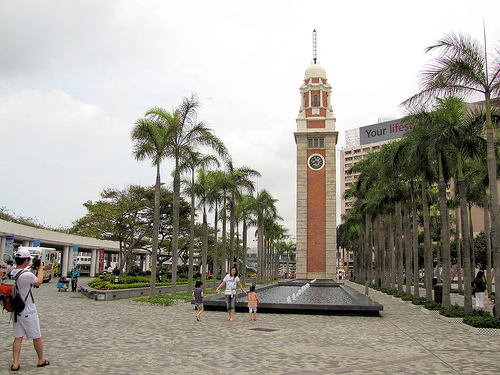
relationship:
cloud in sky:
[5, 86, 132, 190] [2, 2, 499, 225]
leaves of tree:
[421, 32, 485, 66] [404, 24, 499, 327]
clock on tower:
[305, 149, 326, 173] [292, 26, 341, 280]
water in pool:
[224, 282, 355, 304] [191, 277, 384, 313]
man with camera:
[2, 249, 51, 371] [30, 254, 45, 269]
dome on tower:
[303, 61, 328, 83] [292, 26, 341, 280]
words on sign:
[365, 125, 404, 138] [358, 113, 416, 146]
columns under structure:
[59, 247, 76, 281] [2, 217, 207, 256]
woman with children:
[212, 266, 245, 322] [189, 279, 260, 323]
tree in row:
[404, 24, 499, 327] [342, 23, 499, 330]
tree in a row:
[404, 24, 499, 327] [342, 23, 499, 330]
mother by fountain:
[212, 266, 245, 322] [191, 277, 384, 313]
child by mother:
[190, 276, 207, 324] [212, 266, 245, 322]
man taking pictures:
[2, 249, 51, 371] [30, 254, 45, 269]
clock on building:
[305, 149, 326, 173] [292, 26, 341, 280]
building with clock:
[292, 26, 341, 280] [305, 149, 326, 173]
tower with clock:
[292, 26, 341, 280] [305, 149, 326, 173]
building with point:
[292, 26, 341, 280] [308, 27, 321, 65]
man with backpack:
[2, 249, 51, 371] [2, 268, 29, 316]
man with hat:
[2, 249, 51, 371] [15, 245, 36, 260]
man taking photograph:
[2, 249, 51, 371] [30, 254, 45, 269]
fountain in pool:
[275, 273, 321, 305] [191, 277, 384, 313]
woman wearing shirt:
[212, 266, 245, 322] [222, 273, 240, 295]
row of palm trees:
[342, 23, 499, 330] [404, 24, 499, 327]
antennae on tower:
[311, 28, 319, 63] [292, 26, 341, 280]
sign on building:
[358, 113, 416, 146] [341, 98, 499, 283]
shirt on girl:
[245, 291, 260, 305] [245, 285, 260, 323]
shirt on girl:
[192, 288, 205, 303] [190, 276, 207, 324]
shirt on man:
[8, 269, 37, 310] [2, 249, 51, 371]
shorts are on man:
[12, 307, 43, 340] [2, 249, 51, 371]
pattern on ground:
[79, 333, 143, 362] [2, 276, 499, 374]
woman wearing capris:
[212, 266, 245, 322] [226, 294, 236, 313]